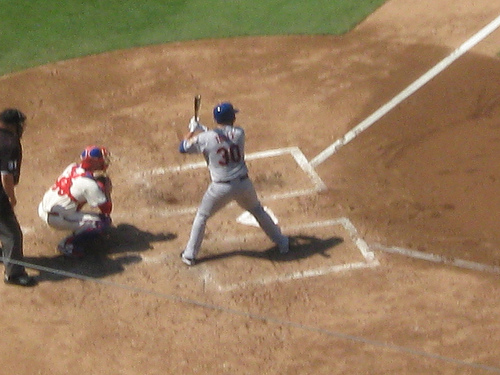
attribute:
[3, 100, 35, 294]
umpire — watching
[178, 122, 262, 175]
grey jersey — light grey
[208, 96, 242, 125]
hat — blue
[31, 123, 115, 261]
uniform — white 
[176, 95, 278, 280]
athlete — group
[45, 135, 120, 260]
athlete — group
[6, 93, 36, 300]
athlete — group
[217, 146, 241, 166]
number 30 — red 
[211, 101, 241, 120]
baseball hat — blue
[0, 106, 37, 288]
umpire — in black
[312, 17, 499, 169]
line — third base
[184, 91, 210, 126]
bat — baseball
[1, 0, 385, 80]
grass — well trimmed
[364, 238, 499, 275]
line — first base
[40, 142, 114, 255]
man — crouched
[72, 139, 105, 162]
hat — blue, red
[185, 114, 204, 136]
gloves — white 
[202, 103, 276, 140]
hat — blue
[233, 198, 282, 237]
base — white 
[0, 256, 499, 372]
cable — thin, grey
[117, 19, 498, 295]
lines — chalk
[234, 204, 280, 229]
plate — home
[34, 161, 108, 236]
uniform — red, white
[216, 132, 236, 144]
writing — red 